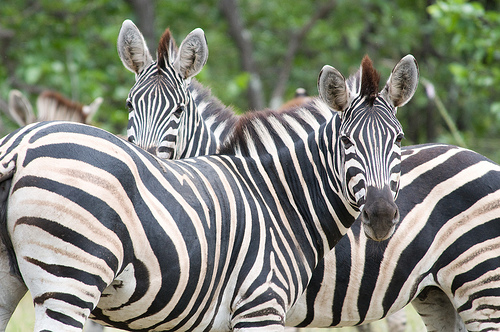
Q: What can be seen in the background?
A: Trees.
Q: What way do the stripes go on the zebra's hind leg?
A: Horizontal.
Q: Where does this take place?
A: Zoo.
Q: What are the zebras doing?
A: Looking at photographer.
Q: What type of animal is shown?
A: Zebra.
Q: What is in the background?
A: Trees.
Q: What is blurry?
A: Background.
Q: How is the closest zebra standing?
A: Sideways.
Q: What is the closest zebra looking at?
A: Camera.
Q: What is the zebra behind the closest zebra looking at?
A: Camera.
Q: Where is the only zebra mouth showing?
A: On the closest zebra.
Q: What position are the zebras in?
A: Standing.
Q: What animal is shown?
A: Zebra.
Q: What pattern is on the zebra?
A: Stripes.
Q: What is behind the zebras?
A: Trees.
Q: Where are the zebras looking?
A: Straight.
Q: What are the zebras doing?
A: Looking at the camera.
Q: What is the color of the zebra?
A: Black and white.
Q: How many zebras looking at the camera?
A: Two.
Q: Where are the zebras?
A: In the zoo.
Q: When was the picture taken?
A: Daytime.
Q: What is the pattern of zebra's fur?
A: Stripes.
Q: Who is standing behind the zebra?
A: No one.